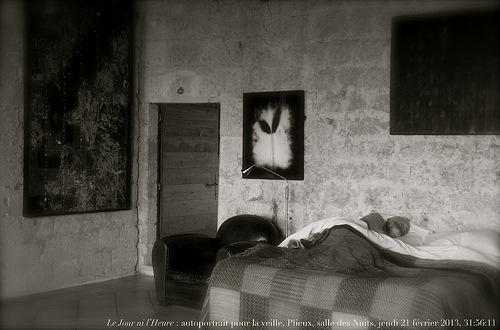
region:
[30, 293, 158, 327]
The tiles on the floor are white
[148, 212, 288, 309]
The chair in the corner is leather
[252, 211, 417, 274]
A man sleeping in the bed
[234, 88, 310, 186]
A picture hanging on the wall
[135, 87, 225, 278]
A door way to another room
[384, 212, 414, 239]
The man has a gray beard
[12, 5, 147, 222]
A very large paining on the wall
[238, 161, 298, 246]
A lamp standing by the bed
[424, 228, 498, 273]
A white pillow on the bed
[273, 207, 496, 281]
The sheet on the bed is white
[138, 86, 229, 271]
doorway to a bedroom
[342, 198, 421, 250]
man sleeping in a bed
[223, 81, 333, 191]
picture frame on a wall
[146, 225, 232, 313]
chair in a bedroom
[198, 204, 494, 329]
bed against a wall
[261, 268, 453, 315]
checkered comforter on bed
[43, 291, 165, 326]
tiled floor in bedroom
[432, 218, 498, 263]
pillow on a bed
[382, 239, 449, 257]
sheets on a bed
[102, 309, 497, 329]
typed description of photo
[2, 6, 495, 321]
the picture is black and white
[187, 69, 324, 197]
picture over the chair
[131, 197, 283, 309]
the chair is dark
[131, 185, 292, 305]
the chair is made of leather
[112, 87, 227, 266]
the door is open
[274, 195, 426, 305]
a man is sleeping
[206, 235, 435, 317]
the blanket is a checkered pattern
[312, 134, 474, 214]
the wall is made with stone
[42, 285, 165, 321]
the floor is tiled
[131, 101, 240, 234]
the door is made of wood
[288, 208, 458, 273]
A man asleep in the bed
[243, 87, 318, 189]
a black and white picture wall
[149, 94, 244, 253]
A wooden door in the opening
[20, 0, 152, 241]
a large black picture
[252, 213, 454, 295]
a checker blanket on the bed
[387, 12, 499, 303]
a picture above the bed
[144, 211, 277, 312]
a black chair beside the bed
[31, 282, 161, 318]
a stone tile floor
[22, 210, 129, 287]
a white stone wall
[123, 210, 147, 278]
A crack in the wall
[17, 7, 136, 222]
large painting on side wall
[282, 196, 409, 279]
person laying inbed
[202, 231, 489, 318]
bedspread with block print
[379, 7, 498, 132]
painting hanging above bed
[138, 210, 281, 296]
chair against wall beside bed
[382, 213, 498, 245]
two white pillows on bed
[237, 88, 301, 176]
painting with black background on wall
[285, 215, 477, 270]
white sheet on bed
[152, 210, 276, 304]
dark colored chair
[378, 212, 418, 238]
person's head on pillow